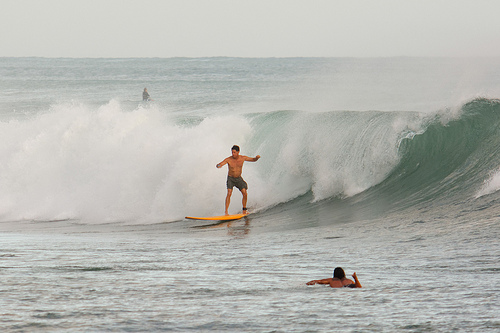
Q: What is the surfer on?
A: A wave.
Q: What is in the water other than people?
A: A wave.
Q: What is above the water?
A: The sky.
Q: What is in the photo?
A: The ocean.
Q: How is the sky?
A: Cloudy.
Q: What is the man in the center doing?
A: Surfing.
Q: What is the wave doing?
A: Splashing.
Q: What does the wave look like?
A: Large and curved over.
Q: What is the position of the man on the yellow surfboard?
A: He is standing.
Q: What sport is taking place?
A: Surfing.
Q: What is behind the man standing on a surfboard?
A: A wave.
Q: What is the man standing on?
A: A surfboard.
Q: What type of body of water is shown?
A: An ocean.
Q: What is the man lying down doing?
A: Paddling out.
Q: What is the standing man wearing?
A: Swim trunks.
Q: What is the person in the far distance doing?
A: Waiting for a wave.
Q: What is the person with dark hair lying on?
A: A surfboard.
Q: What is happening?
A: Surfing.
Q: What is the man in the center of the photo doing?
A: Surfing.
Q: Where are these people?
A: Ocean.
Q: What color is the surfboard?
A: Yellow.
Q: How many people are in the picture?
A: Three.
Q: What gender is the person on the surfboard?
A: Male.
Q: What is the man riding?
A: Surfboard.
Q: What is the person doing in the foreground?
A: Swimming.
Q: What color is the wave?
A: White.